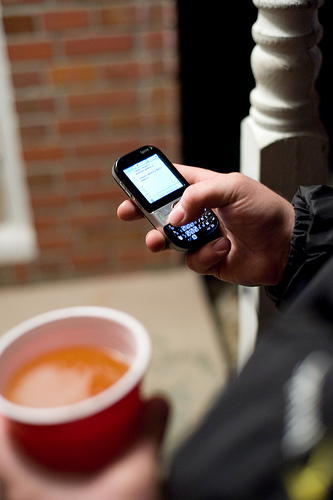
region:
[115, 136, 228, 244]
black and white cell phone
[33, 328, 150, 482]
man holds red cup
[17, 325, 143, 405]
orange liquid in cup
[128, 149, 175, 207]
LCD screen on phone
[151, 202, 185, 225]
grey buttons on phone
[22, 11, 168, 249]
brick wall in background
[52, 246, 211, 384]
grey floor under brick wall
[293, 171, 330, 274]
person has black coat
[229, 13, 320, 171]
white rail behind person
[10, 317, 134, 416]
white rim on red cup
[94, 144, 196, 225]
a small black cellphone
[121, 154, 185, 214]
cellphone with text on it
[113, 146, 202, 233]
cellphone with lit-up screen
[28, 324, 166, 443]
cup with orange liquid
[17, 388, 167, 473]
red circular cup with hand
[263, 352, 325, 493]
white and yellow blurry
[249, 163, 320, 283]
hand with part of jacket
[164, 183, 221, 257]
thumb texting buttons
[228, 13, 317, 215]
white decorative wooden post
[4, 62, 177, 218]
blurry brick wall in back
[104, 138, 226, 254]
A black cell phone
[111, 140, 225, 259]
The phone is on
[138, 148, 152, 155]
The word Sprint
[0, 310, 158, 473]
A blurry drinking cup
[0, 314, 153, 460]
A cup with a beverage in it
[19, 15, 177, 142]
A brick wall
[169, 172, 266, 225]
A right thumb on the hand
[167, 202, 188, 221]
A thumbnail on the thumb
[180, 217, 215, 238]
The keyboard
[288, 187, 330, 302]
A sleeve of a black jacket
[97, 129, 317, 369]
person is holding a cell phone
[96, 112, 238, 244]
the phone is silver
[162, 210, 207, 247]
the buttons are lit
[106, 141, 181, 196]
the screen is on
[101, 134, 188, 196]
the edge of the phone is black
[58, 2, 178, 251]
the wall is blurry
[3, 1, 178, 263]
the wall is made of bricks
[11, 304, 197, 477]
person is holding a cup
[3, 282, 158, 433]
the rim of the cup is white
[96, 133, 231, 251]
this is a cellphone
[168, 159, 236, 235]
this is a thumb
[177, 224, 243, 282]
this is a pinkie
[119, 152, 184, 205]
this is a screen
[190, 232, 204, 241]
this is the number 0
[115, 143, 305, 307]
this is a hand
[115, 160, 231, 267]
these are the fingers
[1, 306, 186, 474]
this is a cup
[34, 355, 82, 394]
this is a drink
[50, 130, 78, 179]
this is a brick